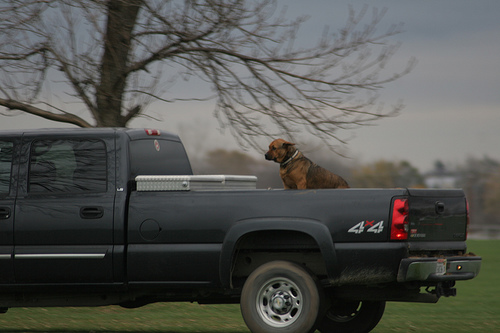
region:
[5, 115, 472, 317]
black truck with a dog in the back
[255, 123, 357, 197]
brown dog in the back of a truck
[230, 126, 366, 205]
brown dog with a white collar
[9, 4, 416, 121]
tree with no leaves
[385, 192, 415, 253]
red brake light on back of truck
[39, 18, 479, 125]
sky covered with grey dark clouds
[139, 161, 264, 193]
silver tool box in back of truck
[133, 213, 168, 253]
gas tank cover on side of truck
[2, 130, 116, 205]
two windows on side of truck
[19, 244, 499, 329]
large field with green grass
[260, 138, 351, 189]
A dog sitting in a truck.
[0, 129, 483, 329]
A large grey truck.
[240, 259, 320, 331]
The wheel of the truck.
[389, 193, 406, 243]
The rear tailight.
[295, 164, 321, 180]
The dog's brown and back fur.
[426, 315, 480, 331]
Part of the green grass.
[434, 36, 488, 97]
Part of the cloudy sky.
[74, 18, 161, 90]
Part of the tree.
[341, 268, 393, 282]
Some dirt on the truck.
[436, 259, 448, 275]
Part of the white license plate.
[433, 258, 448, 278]
a license plate of the truck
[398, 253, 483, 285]
a bumper of the truck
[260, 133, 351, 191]
a brown dog with a white collar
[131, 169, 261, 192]
a silver tool box at the back of the truck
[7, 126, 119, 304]
a door of the truck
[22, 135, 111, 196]
a window of the truck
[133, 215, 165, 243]
an opening where to fill the truck with gas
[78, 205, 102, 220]
a door handle of the truck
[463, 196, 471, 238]
a light at the back of the truck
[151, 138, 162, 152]
a sticker attached on the truck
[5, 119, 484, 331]
a part of the truck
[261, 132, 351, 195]
a dog on the truck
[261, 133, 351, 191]
a brown dog on the truck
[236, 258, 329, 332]
a rear wheel of the truck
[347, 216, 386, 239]
a 4x4 sign on the truck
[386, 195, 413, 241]
a light of the truck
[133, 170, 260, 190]
a tool trunk on the back of the truck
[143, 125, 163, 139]
a light on the truck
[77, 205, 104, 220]
a handle of the truck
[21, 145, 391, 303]
this is a pickup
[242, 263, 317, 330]
this is a the wheel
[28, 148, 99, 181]
this is the door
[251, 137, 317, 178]
this is a door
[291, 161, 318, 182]
the dog is brown in color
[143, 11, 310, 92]
this is a tree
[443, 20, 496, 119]
this is the sky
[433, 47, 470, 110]
the sky is blue in color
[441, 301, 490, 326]
this is a grass area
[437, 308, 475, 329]
the grass is green in color